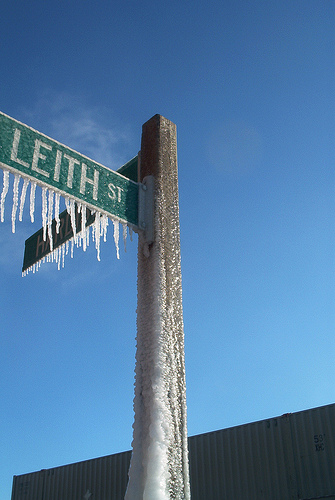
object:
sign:
[0, 111, 138, 225]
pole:
[140, 114, 187, 499]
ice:
[124, 180, 139, 224]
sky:
[2, 2, 333, 62]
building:
[11, 403, 335, 499]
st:
[107, 182, 124, 202]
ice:
[124, 188, 191, 499]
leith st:
[9, 127, 122, 204]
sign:
[20, 155, 146, 272]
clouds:
[0, 85, 125, 170]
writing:
[313, 434, 326, 453]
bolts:
[140, 182, 147, 193]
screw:
[141, 221, 146, 229]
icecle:
[94, 212, 101, 261]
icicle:
[12, 175, 22, 237]